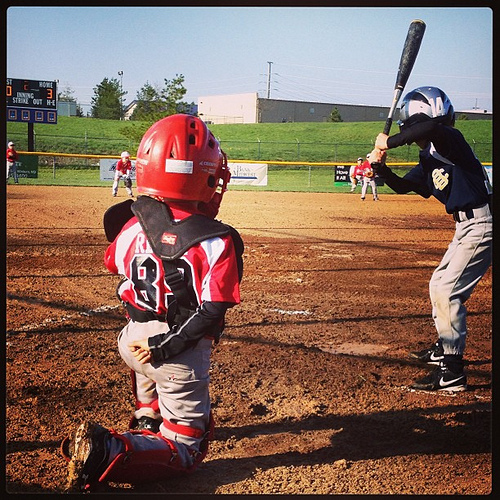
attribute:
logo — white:
[419, 155, 487, 215]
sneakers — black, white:
[413, 340, 465, 393]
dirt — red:
[267, 218, 408, 404]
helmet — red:
[134, 111, 234, 221]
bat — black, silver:
[361, 7, 425, 180]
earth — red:
[5, 174, 492, 496]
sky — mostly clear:
[3, 9, 488, 154]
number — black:
[124, 255, 161, 317]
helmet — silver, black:
[399, 85, 419, 122]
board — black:
[11, 76, 73, 170]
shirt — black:
[369, 119, 497, 208]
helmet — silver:
[396, 86, 459, 130]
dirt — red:
[8, 182, 495, 497]